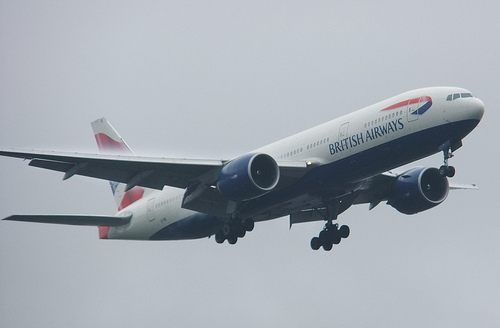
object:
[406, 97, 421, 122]
door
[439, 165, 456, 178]
front wheel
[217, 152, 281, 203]
engine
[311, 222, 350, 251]
wheels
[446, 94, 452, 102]
window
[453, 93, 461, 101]
window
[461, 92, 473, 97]
window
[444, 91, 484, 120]
cockpit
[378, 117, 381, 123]
window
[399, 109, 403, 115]
window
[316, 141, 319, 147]
window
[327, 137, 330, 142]
window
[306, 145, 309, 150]
window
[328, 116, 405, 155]
words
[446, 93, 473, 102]
windshield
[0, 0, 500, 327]
air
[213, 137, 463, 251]
landing gear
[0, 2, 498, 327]
clear sky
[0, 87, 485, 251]
airplane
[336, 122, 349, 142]
door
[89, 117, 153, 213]
tail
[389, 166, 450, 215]
engine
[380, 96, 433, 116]
curve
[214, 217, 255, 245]
wheels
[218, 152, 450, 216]
bottom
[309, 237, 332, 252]
wheel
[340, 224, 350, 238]
wheel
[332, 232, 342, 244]
wheel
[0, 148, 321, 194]
wing